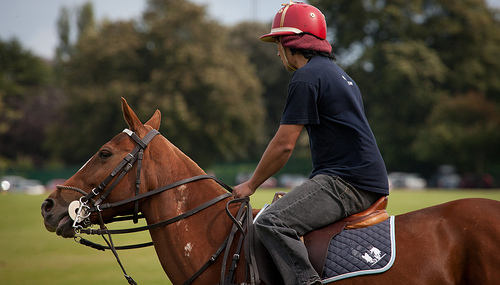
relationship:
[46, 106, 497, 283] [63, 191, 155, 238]
horse wearing bridle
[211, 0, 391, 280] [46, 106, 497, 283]
guy rides horse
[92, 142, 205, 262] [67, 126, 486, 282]
reins on horse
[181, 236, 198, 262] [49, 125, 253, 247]
spots on horse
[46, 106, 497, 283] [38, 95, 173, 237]
horse has head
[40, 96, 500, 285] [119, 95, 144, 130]
horse has ear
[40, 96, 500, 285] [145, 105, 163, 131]
horse has ear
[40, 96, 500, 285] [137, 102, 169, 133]
horse has ear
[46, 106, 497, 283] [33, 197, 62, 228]
horse has nose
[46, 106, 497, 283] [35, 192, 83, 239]
horse has mouth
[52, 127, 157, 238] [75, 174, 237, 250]
bridle has reigns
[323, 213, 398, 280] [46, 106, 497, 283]
blanket on horse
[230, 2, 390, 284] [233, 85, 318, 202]
man has arm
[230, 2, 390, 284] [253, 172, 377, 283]
man has leg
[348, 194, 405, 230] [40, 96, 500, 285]
saddle on horse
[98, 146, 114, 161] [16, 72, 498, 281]
eye on horse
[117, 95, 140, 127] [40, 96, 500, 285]
ear on horse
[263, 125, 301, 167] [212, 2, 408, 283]
elbow on man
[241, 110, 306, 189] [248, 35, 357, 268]
arm of man